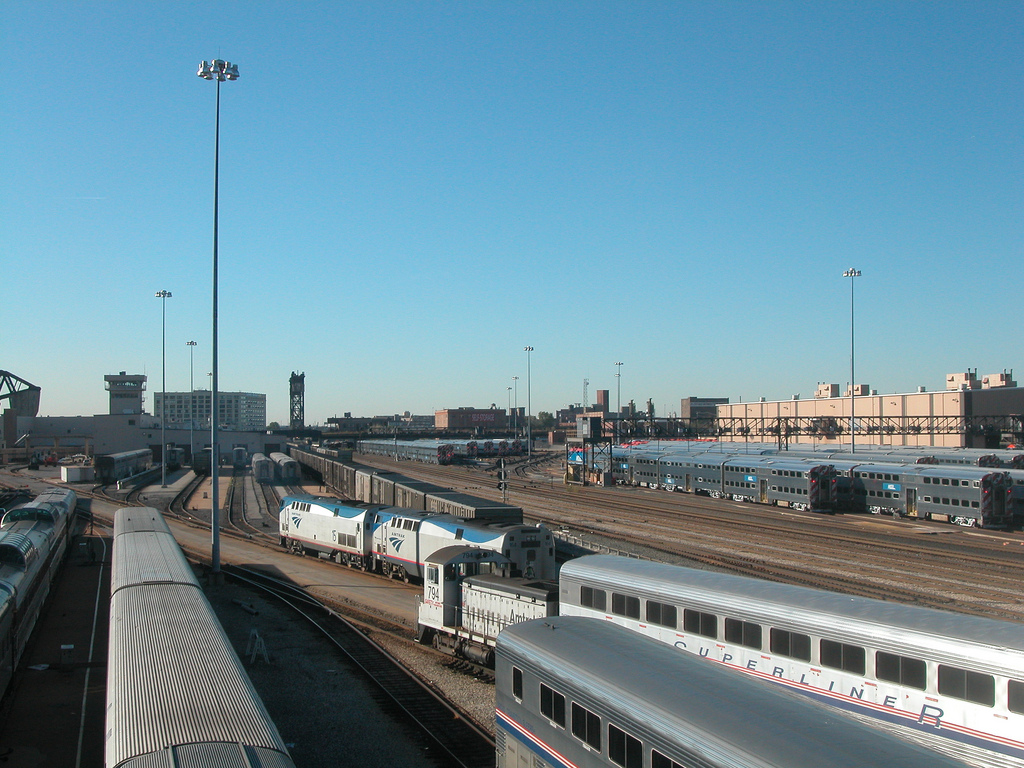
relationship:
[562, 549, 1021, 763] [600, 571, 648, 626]
train has window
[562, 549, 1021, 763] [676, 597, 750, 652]
train has window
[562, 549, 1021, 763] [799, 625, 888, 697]
train has window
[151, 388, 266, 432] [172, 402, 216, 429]
building has window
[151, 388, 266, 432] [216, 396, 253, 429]
building has window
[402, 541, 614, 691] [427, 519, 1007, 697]
engine on train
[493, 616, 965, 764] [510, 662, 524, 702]
train has window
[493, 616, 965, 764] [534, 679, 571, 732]
train has window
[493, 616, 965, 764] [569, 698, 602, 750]
train has window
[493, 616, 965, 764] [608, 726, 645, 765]
train has window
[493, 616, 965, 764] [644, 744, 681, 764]
train has window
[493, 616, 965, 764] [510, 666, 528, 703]
train has window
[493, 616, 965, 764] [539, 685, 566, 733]
train has window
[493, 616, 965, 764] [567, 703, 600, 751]
train has window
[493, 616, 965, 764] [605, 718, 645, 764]
train has window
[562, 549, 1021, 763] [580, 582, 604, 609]
train has window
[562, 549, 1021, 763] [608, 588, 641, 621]
train has window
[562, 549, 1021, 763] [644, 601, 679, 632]
train has window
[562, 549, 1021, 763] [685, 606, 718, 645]
train has window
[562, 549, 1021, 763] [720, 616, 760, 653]
train has window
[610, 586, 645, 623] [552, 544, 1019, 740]
window on train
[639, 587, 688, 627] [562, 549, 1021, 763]
window on train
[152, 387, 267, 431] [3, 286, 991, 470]
building standing in distance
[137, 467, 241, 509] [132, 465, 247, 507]
set of tracks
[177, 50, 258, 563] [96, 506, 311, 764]
light pole above train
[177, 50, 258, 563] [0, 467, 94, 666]
light pole above train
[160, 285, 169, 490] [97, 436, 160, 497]
light pole above train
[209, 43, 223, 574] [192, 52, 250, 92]
light pole has light fixture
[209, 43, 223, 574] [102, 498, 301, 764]
light pole above train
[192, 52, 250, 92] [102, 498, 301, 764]
light fixture above train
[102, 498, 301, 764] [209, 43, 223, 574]
train to left of light pole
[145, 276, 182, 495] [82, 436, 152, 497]
light pole above train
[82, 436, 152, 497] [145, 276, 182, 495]
train to left of light pole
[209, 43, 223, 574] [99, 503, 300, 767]
light pole above train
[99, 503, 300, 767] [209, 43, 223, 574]
train to left of light pole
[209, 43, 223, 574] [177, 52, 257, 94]
light pole has light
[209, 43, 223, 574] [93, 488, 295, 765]
light pole above train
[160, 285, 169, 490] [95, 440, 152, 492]
light pole above train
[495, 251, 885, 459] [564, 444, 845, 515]
light poles above train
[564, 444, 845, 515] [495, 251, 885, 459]
train to left of light poles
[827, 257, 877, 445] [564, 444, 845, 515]
light pole above train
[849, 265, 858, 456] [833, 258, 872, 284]
light pole has light fixture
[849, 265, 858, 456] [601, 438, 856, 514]
light pole above train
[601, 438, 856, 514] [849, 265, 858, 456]
train to left of light pole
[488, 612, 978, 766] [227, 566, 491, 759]
train on track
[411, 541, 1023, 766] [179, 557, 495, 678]
train on track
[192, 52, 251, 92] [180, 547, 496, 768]
light fixture above track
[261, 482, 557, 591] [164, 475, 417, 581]
train on track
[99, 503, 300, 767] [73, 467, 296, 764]
train on track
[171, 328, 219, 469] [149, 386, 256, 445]
light above building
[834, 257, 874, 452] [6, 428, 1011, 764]
light fixture to right of train depot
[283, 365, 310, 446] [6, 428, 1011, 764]
tower behind train depot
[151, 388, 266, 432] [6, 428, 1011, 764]
building behind train depot